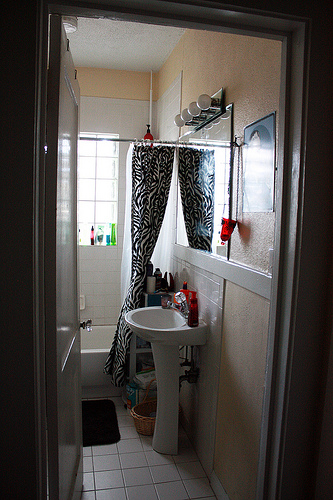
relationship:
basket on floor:
[126, 376, 184, 438] [81, 386, 222, 498]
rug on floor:
[80, 396, 119, 447] [81, 386, 222, 498]